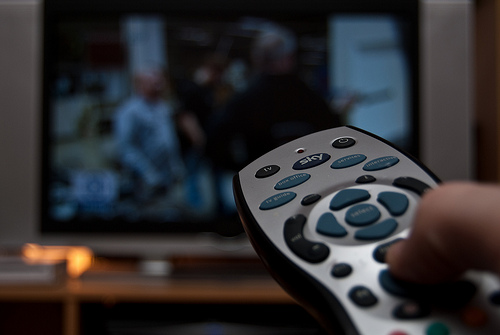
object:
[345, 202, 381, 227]
button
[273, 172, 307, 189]
button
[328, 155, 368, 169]
button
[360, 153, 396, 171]
button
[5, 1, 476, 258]
flatscreen tv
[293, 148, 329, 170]
button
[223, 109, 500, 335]
remote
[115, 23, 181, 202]
people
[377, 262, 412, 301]
button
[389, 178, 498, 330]
person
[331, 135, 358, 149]
power button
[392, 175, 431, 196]
button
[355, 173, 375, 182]
button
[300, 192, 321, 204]
button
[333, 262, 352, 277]
button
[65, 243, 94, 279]
light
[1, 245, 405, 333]
stand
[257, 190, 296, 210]
button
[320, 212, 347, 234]
button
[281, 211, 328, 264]
button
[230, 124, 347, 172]
border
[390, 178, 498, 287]
finger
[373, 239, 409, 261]
button